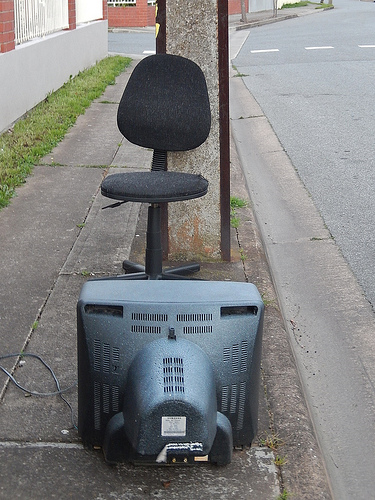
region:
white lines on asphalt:
[249, 42, 373, 52]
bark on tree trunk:
[165, 1, 220, 264]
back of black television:
[78, 277, 263, 467]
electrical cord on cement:
[1, 353, 77, 428]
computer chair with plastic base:
[98, 51, 211, 280]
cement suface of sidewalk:
[2, 52, 330, 498]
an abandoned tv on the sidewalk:
[78, 276, 258, 462]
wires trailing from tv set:
[0, 349, 77, 436]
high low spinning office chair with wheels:
[102, 51, 212, 279]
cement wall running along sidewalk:
[157, 0, 232, 260]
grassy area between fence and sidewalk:
[1, 50, 131, 206]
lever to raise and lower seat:
[100, 202, 130, 214]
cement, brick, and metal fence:
[0, 0, 108, 130]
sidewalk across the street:
[226, 1, 329, 28]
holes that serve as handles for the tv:
[81, 300, 259, 324]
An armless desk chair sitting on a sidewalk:
[99, 52, 211, 282]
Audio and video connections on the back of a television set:
[122, 446, 226, 467]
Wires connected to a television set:
[1, 336, 142, 469]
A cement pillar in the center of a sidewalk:
[126, 0, 288, 269]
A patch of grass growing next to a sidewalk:
[1, 51, 132, 213]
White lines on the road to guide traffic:
[109, 24, 373, 62]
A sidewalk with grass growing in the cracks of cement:
[30, 55, 264, 278]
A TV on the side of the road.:
[75, 275, 263, 464]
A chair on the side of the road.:
[100, 52, 211, 278]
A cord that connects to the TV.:
[1, 351, 77, 431]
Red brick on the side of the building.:
[0, 0, 17, 53]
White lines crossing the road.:
[249, 43, 374, 54]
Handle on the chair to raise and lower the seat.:
[101, 198, 127, 210]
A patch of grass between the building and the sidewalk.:
[0, 53, 132, 205]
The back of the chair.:
[117, 52, 212, 149]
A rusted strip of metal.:
[220, 0, 228, 259]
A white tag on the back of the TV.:
[160, 413, 186, 437]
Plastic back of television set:
[76, 276, 264, 468]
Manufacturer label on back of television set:
[160, 414, 186, 437]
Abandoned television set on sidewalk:
[73, 278, 266, 469]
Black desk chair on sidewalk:
[93, 52, 211, 283]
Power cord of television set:
[0, 351, 77, 434]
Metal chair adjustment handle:
[101, 199, 132, 210]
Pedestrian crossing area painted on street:
[249, 42, 373, 54]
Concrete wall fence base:
[1, 19, 112, 134]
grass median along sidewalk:
[1, 53, 131, 209]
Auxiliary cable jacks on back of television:
[169, 457, 189, 463]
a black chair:
[98, 40, 215, 277]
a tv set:
[4, 283, 270, 474]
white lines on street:
[137, 40, 373, 58]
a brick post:
[150, 2, 232, 261]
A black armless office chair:
[100, 52, 211, 280]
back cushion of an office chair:
[116, 51, 208, 146]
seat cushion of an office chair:
[99, 170, 207, 202]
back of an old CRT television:
[78, 279, 264, 466]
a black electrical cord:
[0, 352, 76, 428]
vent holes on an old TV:
[130, 311, 166, 321]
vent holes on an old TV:
[129, 323, 161, 333]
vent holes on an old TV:
[176, 311, 212, 320]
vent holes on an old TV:
[182, 325, 212, 332]